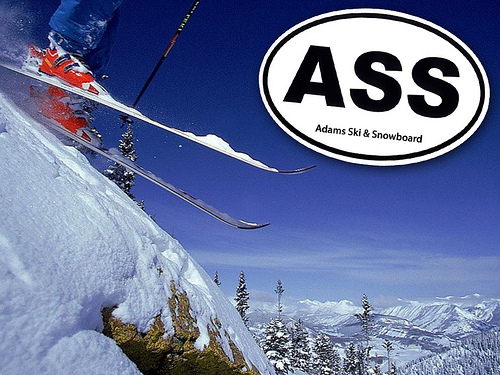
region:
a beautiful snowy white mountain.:
[301, 281, 498, 373]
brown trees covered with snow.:
[238, 285, 404, 374]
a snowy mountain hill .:
[0, 108, 295, 373]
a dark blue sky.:
[308, 183, 454, 244]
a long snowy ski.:
[156, 130, 315, 191]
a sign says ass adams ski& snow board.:
[259, 5, 499, 191]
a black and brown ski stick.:
[139, 1, 212, 90]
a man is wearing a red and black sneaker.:
[18, 28, 117, 108]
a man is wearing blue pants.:
[51, 2, 108, 51]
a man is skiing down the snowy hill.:
[2, 0, 330, 242]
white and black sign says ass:
[286, 23, 413, 135]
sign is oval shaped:
[341, 108, 415, 160]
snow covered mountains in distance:
[430, 285, 469, 336]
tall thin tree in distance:
[356, 290, 382, 350]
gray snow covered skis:
[140, 91, 225, 207]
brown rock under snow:
[153, 290, 225, 327]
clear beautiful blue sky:
[382, 205, 462, 242]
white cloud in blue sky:
[338, 264, 405, 301]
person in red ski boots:
[28, 35, 105, 149]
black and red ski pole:
[115, 26, 210, 79]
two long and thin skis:
[12, 50, 311, 246]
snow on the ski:
[182, 112, 272, 179]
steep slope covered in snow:
[1, 93, 305, 374]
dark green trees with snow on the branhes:
[262, 312, 347, 374]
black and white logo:
[259, 10, 490, 168]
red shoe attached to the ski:
[33, 43, 110, 92]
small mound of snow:
[191, 125, 246, 164]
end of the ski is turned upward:
[222, 204, 279, 239]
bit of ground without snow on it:
[130, 336, 192, 363]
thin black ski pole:
[136, 0, 197, 107]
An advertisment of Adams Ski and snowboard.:
[240, 8, 491, 213]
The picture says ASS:
[228, 13, 459, 198]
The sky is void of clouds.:
[304, 185, 421, 220]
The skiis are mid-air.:
[20, 21, 284, 266]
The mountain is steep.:
[44, 155, 256, 350]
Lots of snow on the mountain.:
[35, 151, 109, 301]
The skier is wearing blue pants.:
[70, 8, 94, 39]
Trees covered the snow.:
[251, 281, 371, 373]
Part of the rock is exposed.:
[120, 305, 247, 357]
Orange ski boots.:
[37, 40, 99, 147]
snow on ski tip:
[200, 113, 295, 184]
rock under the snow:
[108, 295, 242, 374]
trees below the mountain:
[325, 264, 379, 372]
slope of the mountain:
[206, 232, 258, 369]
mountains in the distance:
[333, 273, 495, 371]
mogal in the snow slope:
[127, 238, 189, 298]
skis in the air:
[46, 120, 366, 248]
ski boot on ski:
[18, 110, 106, 148]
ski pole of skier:
[111, 0, 205, 159]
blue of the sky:
[252, 147, 482, 289]